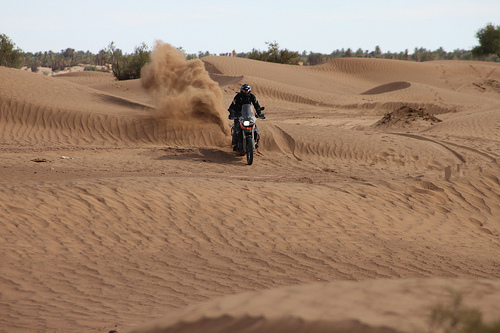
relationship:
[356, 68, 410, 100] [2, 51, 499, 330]
spot on sand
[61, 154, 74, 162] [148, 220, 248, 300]
object on sand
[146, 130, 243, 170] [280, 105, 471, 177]
shadow on sandbank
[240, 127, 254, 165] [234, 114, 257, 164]
tire of bike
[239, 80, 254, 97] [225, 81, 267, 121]
helmet of biker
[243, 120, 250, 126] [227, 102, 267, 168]
headlight of bike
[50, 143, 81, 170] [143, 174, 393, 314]
object in sand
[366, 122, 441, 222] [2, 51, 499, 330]
prints in sand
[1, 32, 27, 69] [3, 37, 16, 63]
tree with green leaves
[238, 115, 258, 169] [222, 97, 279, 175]
tire of a motorcycle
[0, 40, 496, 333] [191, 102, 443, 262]
dune on a beach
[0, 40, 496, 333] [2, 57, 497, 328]
dune on a beach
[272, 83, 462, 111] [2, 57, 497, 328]
dune on a beach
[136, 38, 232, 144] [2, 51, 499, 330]
air-kicked sand of sand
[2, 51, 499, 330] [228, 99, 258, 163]
sand behind motorcycle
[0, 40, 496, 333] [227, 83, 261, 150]
dune in biker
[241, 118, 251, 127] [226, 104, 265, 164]
headlight of motorcycle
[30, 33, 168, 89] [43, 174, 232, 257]
trees behind a sand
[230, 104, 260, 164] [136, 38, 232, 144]
bike send air-kicked sand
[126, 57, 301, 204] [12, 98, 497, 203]
dirt covers patch